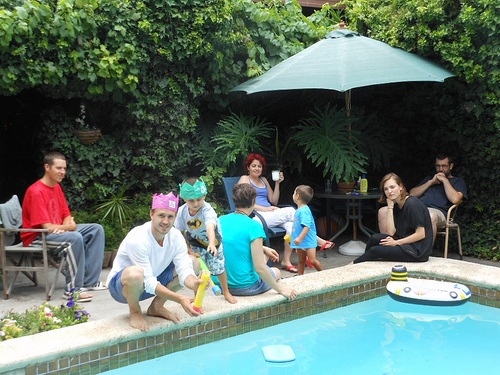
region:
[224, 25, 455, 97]
green umbrella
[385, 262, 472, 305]
white and black floaty in the pool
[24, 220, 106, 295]
gray and white pants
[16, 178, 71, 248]
red shirt on the man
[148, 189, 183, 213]
pink crown on the man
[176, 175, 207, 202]
teal crown on the kid's head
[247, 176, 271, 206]
blue tank top on the woman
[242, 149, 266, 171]
woman with red hair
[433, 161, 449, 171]
man wearing glasses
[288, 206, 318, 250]
blue shirt on the toddler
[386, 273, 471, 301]
round plastic inflatable toy in the pool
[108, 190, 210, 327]
man wearing a pink crown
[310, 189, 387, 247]
glass and metal patio table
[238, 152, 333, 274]
woman with red hair holding a white coffee cup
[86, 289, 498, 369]
part of the water in a swimming pool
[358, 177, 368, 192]
yellow cup on the table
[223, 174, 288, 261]
blue patio chair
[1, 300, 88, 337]
small section of garden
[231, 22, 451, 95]
open blue umbrella on the patio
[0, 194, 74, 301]
gray and metal deck chair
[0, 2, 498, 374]
People sitting around in back yard near pool.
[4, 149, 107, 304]
Man sitting in chair.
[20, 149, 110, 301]
Man wearing red short sleeved shirt.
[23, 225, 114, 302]
Man wearing grey and white striped jogging pants.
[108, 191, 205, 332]
Man wearing purple crown on head.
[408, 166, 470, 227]
Man wearing black t-shirt.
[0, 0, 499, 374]
Round table with large umbrella attached.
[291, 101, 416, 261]
Green plant in brown flower pot on table.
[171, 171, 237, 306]
Small boy wearing green crown.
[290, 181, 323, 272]
Small boy wearing light blue t-shirt.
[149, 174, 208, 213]
Both wearing paper crowns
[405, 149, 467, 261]
Being aloof and detached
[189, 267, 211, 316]
Holding a yellow and pink pool toy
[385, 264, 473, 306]
Floating device in the pool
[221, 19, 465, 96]
Green umbrella to block the sun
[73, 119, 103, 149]
Woven basket planter hanging from a tree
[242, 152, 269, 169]
Dyed her hair deep red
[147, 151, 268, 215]
Ronald Mcdonald hair and burger king hats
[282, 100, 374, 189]
Palms hanging over table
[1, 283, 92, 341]
Bed of flowers by the pool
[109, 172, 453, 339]
they are sitting poolside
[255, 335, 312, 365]
this is a foam board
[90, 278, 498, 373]
this is a swimming pool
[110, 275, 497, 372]
the pool water is bright blue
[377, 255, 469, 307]
this is an inflatable ring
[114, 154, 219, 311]
they are wearing paper crowns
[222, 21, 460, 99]
this is a green umbrella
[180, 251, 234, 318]
there are squirt guns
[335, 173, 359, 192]
this is a pot on the table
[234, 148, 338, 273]
she is holding a white mug